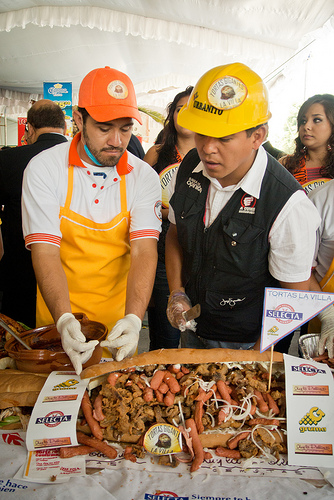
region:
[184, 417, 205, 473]
An orange carrot or chili pepper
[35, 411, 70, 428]
A red and blue selecta label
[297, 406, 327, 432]
A yellow corporate logo on a white tag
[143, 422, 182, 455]
A yellow tortas label in front of a giant sandwich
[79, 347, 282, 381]
Half a loaf of bread that makes up the sandwich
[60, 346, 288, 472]
A very large sandwich with unknown substance inside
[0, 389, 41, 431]
A small sandwich next to a larger one.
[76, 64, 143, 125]
An orange baseball cap on someone's head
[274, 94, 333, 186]
A hispanic lady looking at something.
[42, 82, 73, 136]
A corona advertisement hanging from the ceiling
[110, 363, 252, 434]
food under the people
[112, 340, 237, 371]
brown food in photo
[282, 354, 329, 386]
design on the paper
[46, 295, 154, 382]
gloves on person's hand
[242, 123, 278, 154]
ear of the man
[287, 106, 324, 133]
eyes of the girl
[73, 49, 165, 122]
orange hat on man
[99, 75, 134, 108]
logo on the hat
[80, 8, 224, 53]
white roof in the photo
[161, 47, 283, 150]
yellow hat on the man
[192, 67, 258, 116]
sticker on the helmet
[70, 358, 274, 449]
food under the people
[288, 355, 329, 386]
writing on the paper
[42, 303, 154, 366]
hands of the person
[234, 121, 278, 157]
ear of the man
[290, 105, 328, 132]
eyes of the girl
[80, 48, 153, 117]
orange hat on man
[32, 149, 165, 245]
white and orange shirt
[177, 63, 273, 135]
a yellow hard hat on a man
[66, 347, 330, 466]
a massive meat filled sub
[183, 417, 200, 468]
a bent pink hot dog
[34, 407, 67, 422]
the selecta brand logo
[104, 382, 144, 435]
pulled brown beef in a sub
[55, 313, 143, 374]
white gloves on a man's hands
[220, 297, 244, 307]
white cursive signature on a man's apron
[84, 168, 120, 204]
orange buttons on a man's shirt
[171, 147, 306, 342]
a black vest on a man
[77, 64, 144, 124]
an orange cap on a man's head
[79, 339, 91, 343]
part of a glove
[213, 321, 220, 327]
part of a jacket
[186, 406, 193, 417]
part of a carrot